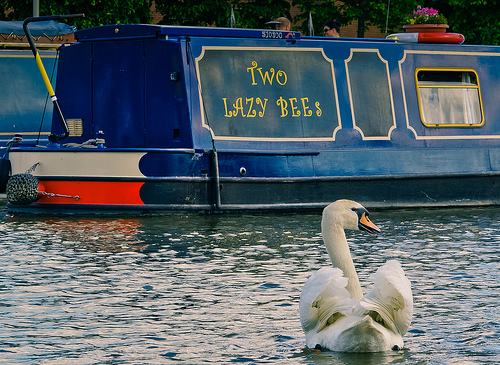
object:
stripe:
[6, 150, 149, 179]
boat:
[4, 14, 500, 211]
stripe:
[39, 181, 146, 208]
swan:
[298, 197, 413, 353]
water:
[0, 208, 500, 365]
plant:
[402, 4, 450, 36]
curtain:
[418, 81, 483, 126]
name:
[218, 60, 325, 119]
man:
[321, 22, 344, 38]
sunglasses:
[323, 27, 336, 33]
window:
[413, 68, 487, 126]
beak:
[359, 214, 382, 235]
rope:
[4, 172, 40, 205]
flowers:
[410, 5, 444, 19]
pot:
[403, 25, 451, 34]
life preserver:
[382, 32, 467, 45]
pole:
[21, 11, 87, 144]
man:
[265, 15, 294, 34]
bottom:
[9, 198, 500, 213]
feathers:
[298, 260, 355, 337]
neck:
[320, 226, 364, 297]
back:
[340, 313, 396, 350]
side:
[178, 39, 498, 211]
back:
[7, 23, 197, 213]